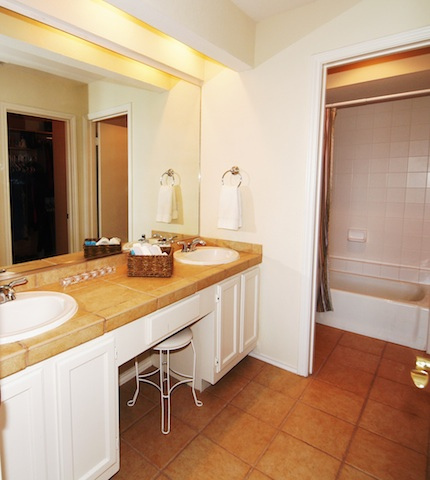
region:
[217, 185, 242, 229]
a white hanging folded towel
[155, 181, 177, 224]
reflection of a white hanging folded towel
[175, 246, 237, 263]
a white porcelain bathroom sink basin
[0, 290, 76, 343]
a white porcelain bathroom sink basin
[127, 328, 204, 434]
a small white stool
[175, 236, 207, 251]
a chrome bathroom sink faucet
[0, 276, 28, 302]
a chrome bathroom sink faucet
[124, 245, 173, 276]
a brown wicker basket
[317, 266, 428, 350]
a white porcelain bath tub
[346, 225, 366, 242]
a white soap holder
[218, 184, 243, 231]
White hand towel hanging on a silver rack.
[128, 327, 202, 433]
Small white bench under a counter.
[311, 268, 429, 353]
White bathtub in the next room.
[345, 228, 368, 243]
White soap holder on the wall.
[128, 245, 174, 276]
Little brown basket on the counter.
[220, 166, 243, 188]
Silver round towel holder on the wall.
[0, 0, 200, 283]
Very large mirror of the bathroom counter.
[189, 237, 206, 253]
Silver faucet over a white sink on the right of the counter.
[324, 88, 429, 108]
A white shower curtain rod.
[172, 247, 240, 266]
White sink to the far right of another.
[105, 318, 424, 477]
The floor is tiled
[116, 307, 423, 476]
The tile is brown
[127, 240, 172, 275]
Square brown basket on counter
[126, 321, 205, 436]
White stool under counter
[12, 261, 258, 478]
The cabinets are white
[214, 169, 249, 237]
White towel hanging from hook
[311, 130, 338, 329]
The shower curtain is brown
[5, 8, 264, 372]
Mirror above the counter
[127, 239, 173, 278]
White towels in basket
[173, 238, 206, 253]
The faucet is silver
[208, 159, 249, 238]
Hand towel on the wall.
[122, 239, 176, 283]
Basket of bathroom products.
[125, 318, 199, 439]
White stool beneath the sink.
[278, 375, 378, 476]
Brown tiles on the floor.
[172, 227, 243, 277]
White sink in the corner.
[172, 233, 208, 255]
Silver handles on the sink/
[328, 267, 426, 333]
White tub in the next room.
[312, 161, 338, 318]
Part of the shower curtain.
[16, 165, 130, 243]
Large mirror over the sink.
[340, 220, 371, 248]
Place to hold the soap.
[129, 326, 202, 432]
There is a white stool under the counter.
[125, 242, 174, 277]
A basket of towels next to the sink.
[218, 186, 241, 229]
A white hand towel hanging from the wall.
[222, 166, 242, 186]
A silver ring with a white hand towel hanging from it.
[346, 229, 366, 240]
White soap holder in the shower.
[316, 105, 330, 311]
Brown shower curtain in the shower.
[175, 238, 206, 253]
The sink faucet is silver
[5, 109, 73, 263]
There is a reflection of the closet in the mirror.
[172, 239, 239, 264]
The sink is white.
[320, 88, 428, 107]
White shower curtain rod holding shower curtain.